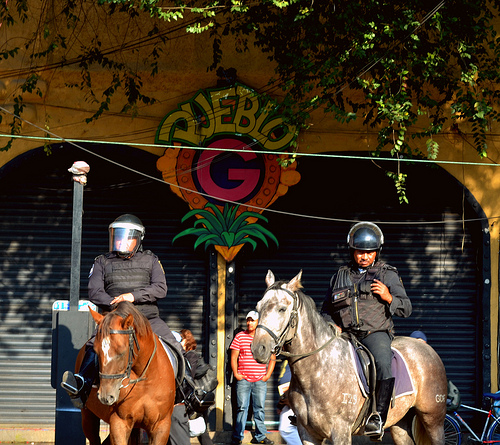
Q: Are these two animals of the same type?
A: Yes, all the animals are horses.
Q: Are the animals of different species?
A: No, all the animals are horses.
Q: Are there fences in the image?
A: No, there are no fences.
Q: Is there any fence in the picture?
A: No, there are no fences.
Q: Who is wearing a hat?
A: The man is wearing a hat.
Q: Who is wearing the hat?
A: The man is wearing a hat.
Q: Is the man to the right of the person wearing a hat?
A: Yes, the man is wearing a hat.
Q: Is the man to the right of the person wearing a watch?
A: No, the man is wearing a hat.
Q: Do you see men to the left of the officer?
A: Yes, there is a man to the left of the officer.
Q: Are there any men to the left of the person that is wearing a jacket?
A: Yes, there is a man to the left of the officer.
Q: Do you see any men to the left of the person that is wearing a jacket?
A: Yes, there is a man to the left of the officer.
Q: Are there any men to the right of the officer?
A: No, the man is to the left of the officer.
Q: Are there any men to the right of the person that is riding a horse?
A: No, the man is to the left of the officer.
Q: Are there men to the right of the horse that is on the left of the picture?
A: Yes, there is a man to the right of the horse.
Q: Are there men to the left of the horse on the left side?
A: No, the man is to the right of the horse.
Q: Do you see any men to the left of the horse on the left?
A: No, the man is to the right of the horse.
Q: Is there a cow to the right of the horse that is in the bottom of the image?
A: No, there is a man to the right of the horse.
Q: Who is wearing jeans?
A: The man is wearing jeans.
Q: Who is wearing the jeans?
A: The man is wearing jeans.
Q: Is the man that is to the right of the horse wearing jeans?
A: Yes, the man is wearing jeans.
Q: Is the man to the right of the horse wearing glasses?
A: No, the man is wearing jeans.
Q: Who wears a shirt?
A: The man wears a shirt.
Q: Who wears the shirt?
A: The man wears a shirt.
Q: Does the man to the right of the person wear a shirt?
A: Yes, the man wears a shirt.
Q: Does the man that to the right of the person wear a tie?
A: No, the man wears a shirt.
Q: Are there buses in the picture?
A: No, there are no buses.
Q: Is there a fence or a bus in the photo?
A: No, there are no buses or fences.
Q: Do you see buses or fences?
A: No, there are no buses or fences.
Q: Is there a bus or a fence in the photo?
A: No, there are no buses or fences.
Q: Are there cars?
A: No, there are no cars.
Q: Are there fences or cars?
A: No, there are no cars or fences.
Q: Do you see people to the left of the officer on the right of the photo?
A: Yes, there is a person to the left of the officer.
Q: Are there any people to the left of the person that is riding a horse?
A: Yes, there is a person to the left of the officer.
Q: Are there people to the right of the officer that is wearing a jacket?
A: No, the person is to the left of the officer.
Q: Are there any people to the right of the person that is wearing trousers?
A: No, the person is to the left of the officer.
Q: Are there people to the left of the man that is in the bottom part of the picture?
A: Yes, there is a person to the left of the man.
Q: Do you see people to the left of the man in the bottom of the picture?
A: Yes, there is a person to the left of the man.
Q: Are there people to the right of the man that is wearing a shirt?
A: No, the person is to the left of the man.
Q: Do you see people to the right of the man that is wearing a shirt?
A: No, the person is to the left of the man.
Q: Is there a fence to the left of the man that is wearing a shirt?
A: No, there is a person to the left of the man.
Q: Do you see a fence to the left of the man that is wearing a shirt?
A: No, there is a person to the left of the man.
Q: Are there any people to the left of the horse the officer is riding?
A: Yes, there is a person to the left of the horse.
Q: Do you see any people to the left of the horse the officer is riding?
A: Yes, there is a person to the left of the horse.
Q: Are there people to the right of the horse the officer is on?
A: No, the person is to the left of the horse.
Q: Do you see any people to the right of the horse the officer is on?
A: No, the person is to the left of the horse.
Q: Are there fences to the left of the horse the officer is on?
A: No, there is a person to the left of the horse.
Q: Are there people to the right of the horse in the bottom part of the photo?
A: Yes, there is a person to the right of the horse.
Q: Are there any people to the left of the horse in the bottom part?
A: No, the person is to the right of the horse.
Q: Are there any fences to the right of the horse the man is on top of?
A: No, there is a person to the right of the horse.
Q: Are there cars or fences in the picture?
A: No, there are no fences or cars.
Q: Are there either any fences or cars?
A: No, there are no fences or cars.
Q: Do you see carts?
A: No, there are no carts.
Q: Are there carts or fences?
A: No, there are no carts or fences.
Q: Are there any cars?
A: No, there are no cars.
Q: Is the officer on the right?
A: Yes, the officer is on the right of the image.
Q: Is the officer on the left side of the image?
A: No, the officer is on the right of the image.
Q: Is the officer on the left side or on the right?
A: The officer is on the right of the image.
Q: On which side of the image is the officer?
A: The officer is on the right of the image.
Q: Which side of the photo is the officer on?
A: The officer is on the right of the image.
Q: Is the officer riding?
A: Yes, the officer is riding.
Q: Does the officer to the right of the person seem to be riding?
A: Yes, the officer is riding.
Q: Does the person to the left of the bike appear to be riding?
A: Yes, the officer is riding.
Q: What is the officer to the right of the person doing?
A: The officer is riding.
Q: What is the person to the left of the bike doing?
A: The officer is riding.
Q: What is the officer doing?
A: The officer is riding.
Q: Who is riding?
A: The officer is riding.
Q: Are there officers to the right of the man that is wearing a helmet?
A: Yes, there is an officer to the right of the man.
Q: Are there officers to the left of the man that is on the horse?
A: No, the officer is to the right of the man.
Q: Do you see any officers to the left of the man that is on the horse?
A: No, the officer is to the right of the man.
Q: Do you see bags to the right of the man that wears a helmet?
A: No, there is an officer to the right of the man.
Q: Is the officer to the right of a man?
A: Yes, the officer is to the right of a man.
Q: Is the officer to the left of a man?
A: No, the officer is to the right of a man.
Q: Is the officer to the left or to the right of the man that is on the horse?
A: The officer is to the right of the man.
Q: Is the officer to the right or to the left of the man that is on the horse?
A: The officer is to the right of the man.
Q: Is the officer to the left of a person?
A: No, the officer is to the right of a person.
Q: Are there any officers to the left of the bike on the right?
A: Yes, there is an officer to the left of the bike.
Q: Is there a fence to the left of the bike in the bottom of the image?
A: No, there is an officer to the left of the bike.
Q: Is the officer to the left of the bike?
A: Yes, the officer is to the left of the bike.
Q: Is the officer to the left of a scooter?
A: No, the officer is to the left of the bike.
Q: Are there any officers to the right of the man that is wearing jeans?
A: Yes, there is an officer to the right of the man.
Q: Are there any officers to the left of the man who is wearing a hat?
A: No, the officer is to the right of the man.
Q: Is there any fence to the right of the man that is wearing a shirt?
A: No, there is an officer to the right of the man.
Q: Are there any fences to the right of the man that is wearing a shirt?
A: No, there is an officer to the right of the man.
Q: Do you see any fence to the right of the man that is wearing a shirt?
A: No, there is an officer to the right of the man.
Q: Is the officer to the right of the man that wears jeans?
A: Yes, the officer is to the right of the man.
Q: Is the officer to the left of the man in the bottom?
A: No, the officer is to the right of the man.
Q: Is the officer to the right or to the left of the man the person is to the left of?
A: The officer is to the right of the man.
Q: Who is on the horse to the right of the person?
A: The officer is on the horse.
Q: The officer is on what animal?
A: The officer is on the horse.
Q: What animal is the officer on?
A: The officer is on the horse.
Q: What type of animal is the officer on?
A: The officer is on the horse.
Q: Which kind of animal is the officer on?
A: The officer is on the horse.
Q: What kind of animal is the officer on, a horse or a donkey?
A: The officer is on a horse.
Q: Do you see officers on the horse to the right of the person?
A: Yes, there is an officer on the horse.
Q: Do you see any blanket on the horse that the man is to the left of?
A: No, there is an officer on the horse.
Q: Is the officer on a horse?
A: Yes, the officer is on a horse.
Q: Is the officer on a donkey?
A: No, the officer is on a horse.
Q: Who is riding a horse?
A: The officer is riding a horse.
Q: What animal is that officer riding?
A: The officer is riding a horse.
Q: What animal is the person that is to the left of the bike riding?
A: The officer is riding a horse.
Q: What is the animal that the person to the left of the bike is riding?
A: The animal is a horse.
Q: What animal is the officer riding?
A: The officer is riding a horse.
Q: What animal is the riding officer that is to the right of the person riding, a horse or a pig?
A: The officer is riding a horse.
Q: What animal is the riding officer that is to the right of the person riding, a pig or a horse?
A: The officer is riding a horse.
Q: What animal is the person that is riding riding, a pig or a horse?
A: The officer is riding a horse.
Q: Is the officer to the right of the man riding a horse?
A: Yes, the officer is riding a horse.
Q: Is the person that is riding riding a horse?
A: Yes, the officer is riding a horse.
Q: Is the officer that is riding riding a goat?
A: No, the officer is riding a horse.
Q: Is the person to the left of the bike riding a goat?
A: No, the officer is riding a horse.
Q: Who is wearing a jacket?
A: The officer is wearing a jacket.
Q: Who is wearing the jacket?
A: The officer is wearing a jacket.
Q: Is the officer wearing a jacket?
A: Yes, the officer is wearing a jacket.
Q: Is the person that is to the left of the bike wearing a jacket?
A: Yes, the officer is wearing a jacket.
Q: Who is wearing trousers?
A: The officer is wearing trousers.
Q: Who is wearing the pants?
A: The officer is wearing trousers.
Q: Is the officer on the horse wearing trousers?
A: Yes, the officer is wearing trousers.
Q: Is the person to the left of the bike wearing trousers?
A: Yes, the officer is wearing trousers.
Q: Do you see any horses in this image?
A: Yes, there is a horse.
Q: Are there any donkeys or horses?
A: Yes, there is a horse.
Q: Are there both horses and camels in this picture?
A: No, there is a horse but no camels.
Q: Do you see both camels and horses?
A: No, there is a horse but no camels.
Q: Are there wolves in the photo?
A: No, there are no wolves.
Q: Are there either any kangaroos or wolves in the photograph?
A: No, there are no wolves or kangaroos.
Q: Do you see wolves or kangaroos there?
A: No, there are no wolves or kangaroos.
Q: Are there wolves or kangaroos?
A: No, there are no wolves or kangaroos.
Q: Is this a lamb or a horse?
A: This is a horse.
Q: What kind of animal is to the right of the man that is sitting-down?
A: The animal is a horse.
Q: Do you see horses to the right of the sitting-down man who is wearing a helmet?
A: Yes, there is a horse to the right of the man.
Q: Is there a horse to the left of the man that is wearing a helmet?
A: No, the horse is to the right of the man.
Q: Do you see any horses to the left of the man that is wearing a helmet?
A: No, the horse is to the right of the man.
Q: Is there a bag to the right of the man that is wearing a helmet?
A: No, there is a horse to the right of the man.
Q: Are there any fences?
A: No, there are no fences.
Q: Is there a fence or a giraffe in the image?
A: No, there are no fences or giraffes.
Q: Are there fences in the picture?
A: No, there are no fences.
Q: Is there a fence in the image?
A: No, there are no fences.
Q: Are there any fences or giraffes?
A: No, there are no fences or giraffes.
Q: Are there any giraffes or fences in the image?
A: No, there are no fences or giraffes.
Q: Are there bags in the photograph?
A: No, there are no bags.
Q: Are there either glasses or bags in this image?
A: No, there are no bags or glasses.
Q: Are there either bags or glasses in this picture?
A: No, there are no bags or glasses.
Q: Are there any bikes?
A: Yes, there is a bike.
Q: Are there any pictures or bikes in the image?
A: Yes, there is a bike.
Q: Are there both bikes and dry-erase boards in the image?
A: No, there is a bike but no dry-erase boards.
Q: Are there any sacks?
A: No, there are no sacks.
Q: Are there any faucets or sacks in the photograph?
A: No, there are no sacks or faucets.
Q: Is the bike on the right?
A: Yes, the bike is on the right of the image.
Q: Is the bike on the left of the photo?
A: No, the bike is on the right of the image.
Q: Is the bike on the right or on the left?
A: The bike is on the right of the image.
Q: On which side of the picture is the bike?
A: The bike is on the right of the image.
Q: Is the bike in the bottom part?
A: Yes, the bike is in the bottom of the image.